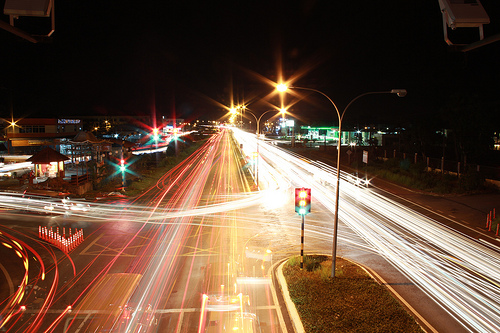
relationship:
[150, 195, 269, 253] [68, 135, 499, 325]
lights on road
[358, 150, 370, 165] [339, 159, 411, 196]
sign on ground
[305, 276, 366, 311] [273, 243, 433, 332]
grass in median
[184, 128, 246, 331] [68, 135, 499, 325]
lanes in road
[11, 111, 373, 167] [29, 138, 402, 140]
buildings in background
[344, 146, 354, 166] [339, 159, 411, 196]
pole on ground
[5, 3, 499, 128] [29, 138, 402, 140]
sky in background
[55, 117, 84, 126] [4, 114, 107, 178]
words on building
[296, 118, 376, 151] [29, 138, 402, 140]
gas station in background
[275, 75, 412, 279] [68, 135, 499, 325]
street light over road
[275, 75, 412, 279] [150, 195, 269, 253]
street light over lights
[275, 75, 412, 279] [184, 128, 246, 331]
street light over lanes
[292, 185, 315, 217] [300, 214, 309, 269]
stop light on pole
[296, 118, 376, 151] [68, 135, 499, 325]
gas station by road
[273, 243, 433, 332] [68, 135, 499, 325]
median of road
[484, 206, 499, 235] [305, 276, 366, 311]
street cones in grass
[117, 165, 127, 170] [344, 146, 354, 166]
light on pole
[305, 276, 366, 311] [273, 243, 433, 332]
grass on median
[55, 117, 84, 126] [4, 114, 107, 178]
words on side of building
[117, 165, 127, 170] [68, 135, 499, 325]
light on road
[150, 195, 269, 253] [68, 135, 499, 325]
lights above road